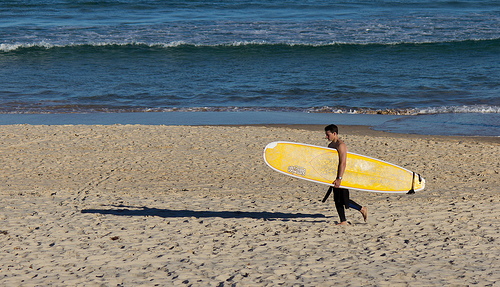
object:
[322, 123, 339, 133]
hair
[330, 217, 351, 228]
foot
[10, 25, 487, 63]
wave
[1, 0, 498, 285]
beach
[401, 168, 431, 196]
tail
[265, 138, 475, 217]
yellow board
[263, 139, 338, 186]
surfboard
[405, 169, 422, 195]
leash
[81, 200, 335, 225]
shadow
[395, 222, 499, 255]
footprints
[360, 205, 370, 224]
foot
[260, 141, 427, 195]
board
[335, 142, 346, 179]
arms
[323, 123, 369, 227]
man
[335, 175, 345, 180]
watch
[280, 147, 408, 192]
spots